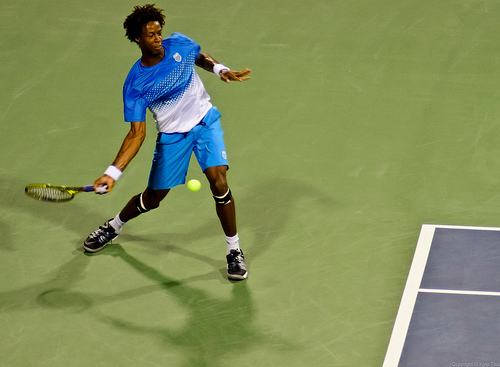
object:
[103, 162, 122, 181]
sweat band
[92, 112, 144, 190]
arm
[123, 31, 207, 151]
jersey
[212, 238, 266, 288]
tennis shoe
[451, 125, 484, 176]
ground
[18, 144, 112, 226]
racquet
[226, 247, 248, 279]
shoe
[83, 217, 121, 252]
shoe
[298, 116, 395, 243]
grass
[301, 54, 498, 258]
pavement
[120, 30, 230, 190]
uniform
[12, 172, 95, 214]
racket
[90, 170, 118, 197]
hand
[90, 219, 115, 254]
tennis shoe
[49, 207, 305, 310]
shoes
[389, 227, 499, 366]
square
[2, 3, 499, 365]
grass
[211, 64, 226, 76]
wrist band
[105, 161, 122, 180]
wrist band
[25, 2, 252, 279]
player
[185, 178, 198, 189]
tennis ball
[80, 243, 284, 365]
shadow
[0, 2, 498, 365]
court